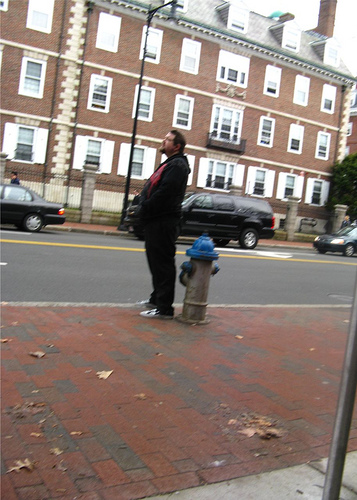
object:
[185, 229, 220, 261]
top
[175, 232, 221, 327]
hydrant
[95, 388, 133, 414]
bricks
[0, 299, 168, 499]
sidewalk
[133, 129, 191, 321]
man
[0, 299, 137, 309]
curb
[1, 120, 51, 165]
shutters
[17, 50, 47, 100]
window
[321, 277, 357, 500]
pole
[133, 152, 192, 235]
hoodie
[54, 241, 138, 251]
line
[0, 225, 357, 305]
road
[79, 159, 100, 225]
column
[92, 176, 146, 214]
fence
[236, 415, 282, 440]
leaves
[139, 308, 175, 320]
shoes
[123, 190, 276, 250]
suv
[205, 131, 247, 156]
balcony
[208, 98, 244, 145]
window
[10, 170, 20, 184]
person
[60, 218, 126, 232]
sidewalk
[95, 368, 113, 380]
leaf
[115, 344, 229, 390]
ground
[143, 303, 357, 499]
side walk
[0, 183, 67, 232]
car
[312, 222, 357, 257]
car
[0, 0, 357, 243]
building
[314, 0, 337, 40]
chimney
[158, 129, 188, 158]
upward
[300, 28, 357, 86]
roof